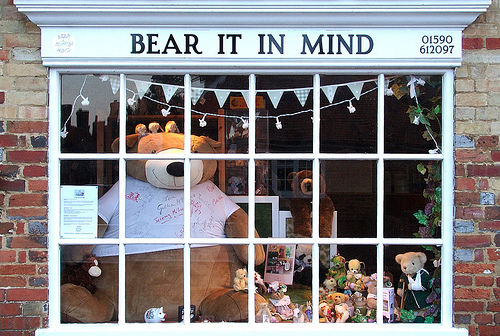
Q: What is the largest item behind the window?
A: Huge stuffed bear.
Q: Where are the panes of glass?
A: Showroom window.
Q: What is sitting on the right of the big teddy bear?
A: Selection little bears.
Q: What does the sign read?
A: "Bear it in mind".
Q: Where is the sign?
A: Above the window.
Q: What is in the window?
A: A big brown bear and smaller bears.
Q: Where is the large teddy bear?
A: In the window.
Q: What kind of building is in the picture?
A: A brick building.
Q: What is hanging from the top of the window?
A: Lights and a streamer.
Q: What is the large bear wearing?
A: A white shirt.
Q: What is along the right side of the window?
A: A vine.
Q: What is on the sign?
A: Black letters.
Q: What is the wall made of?
A: A red brick wall.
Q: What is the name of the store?
A: Bear It In Mind.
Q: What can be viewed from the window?
A: A large bear with a variety of other bears.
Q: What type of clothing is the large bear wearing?
A: A white t-shirt.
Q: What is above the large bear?
A: Triangular decorations hanging from ceiling.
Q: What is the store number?
A: 01590 612097.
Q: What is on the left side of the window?
A: A piece of paper with writing stuck to the window.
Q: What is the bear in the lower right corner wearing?
A: A black and white suit.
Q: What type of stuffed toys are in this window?
A: Bears.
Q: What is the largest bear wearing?
A: A white t-shirt.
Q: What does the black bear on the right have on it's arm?
A: A sling.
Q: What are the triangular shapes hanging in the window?
A: Bunting.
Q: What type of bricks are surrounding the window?
A: Red house bricks.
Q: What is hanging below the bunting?
A: Small fairy lights.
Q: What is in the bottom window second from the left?
A: A pig.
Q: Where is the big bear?
A: In window.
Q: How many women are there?
A: None.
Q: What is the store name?
A: Bear it in mind.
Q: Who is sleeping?
A: No one.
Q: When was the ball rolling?
A: No ball.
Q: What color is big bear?
A: Brown.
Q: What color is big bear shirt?
A: White.